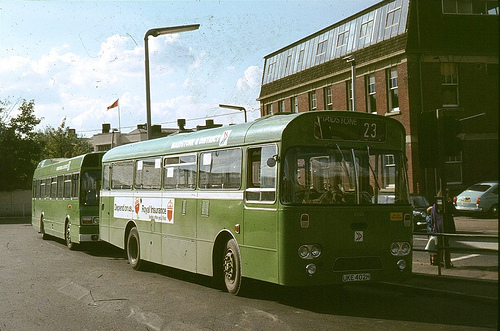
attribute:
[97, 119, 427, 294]
city bus — green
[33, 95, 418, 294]
school buses — green, old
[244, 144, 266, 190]
windows — open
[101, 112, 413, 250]
bus — green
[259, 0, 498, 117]
building — brick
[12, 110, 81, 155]
trees — leafy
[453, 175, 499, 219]
little car — blue